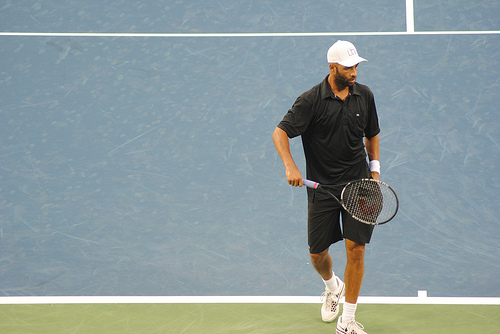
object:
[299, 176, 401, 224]
racket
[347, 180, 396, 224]
string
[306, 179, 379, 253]
shorts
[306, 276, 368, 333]
shoes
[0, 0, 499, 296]
green/blue surface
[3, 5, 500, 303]
white boundary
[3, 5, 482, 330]
tennis-courts surface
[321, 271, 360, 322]
white socks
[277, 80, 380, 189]
black shirt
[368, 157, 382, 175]
white wristband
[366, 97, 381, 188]
man's arm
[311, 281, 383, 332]
man's feet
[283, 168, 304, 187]
hand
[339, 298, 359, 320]
white sock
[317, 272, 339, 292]
white sock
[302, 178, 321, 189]
tennis-racket handle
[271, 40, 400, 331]
man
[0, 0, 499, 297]
blue-from-green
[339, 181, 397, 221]
strings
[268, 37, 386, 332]
tennis player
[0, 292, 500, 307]
white line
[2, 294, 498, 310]
lines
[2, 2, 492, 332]
court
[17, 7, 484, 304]
wall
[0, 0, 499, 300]
building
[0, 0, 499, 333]
field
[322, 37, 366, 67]
cap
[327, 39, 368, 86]
head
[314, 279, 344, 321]
shoe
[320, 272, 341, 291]
sox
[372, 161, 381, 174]
wrist